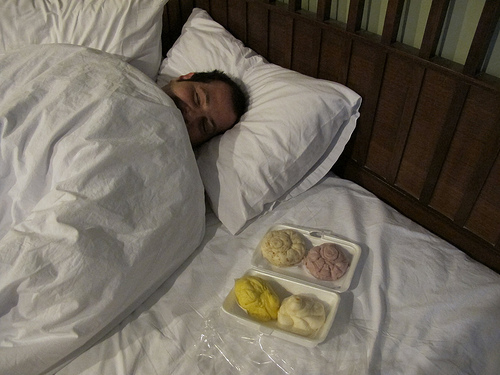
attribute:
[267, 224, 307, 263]
pastry — green colored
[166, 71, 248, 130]
head — mans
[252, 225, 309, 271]
pastry — green spiraled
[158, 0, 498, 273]
headboard — dark, hardwood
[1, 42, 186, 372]
white comforter — all white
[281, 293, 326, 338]
pastry — white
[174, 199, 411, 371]
container — plastic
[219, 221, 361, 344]
container — plastic, styrofoam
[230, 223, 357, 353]
container — plastic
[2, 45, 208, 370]
comforter — white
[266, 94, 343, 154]
pillow — part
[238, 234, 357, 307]
pastry — white, spiral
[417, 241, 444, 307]
sheet — part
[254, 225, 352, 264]
pastry. — pink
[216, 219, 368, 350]
container — Plastic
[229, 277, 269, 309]
pastry — yellow